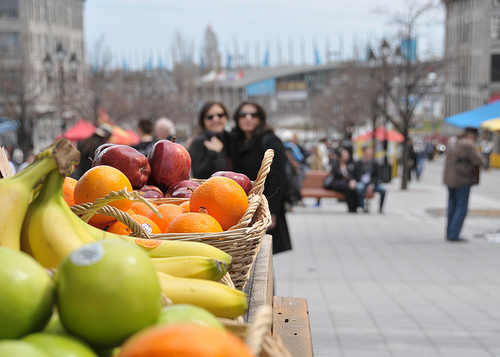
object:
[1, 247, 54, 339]
apple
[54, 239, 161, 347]
apple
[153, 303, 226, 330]
apple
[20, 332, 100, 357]
apple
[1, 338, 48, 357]
apple